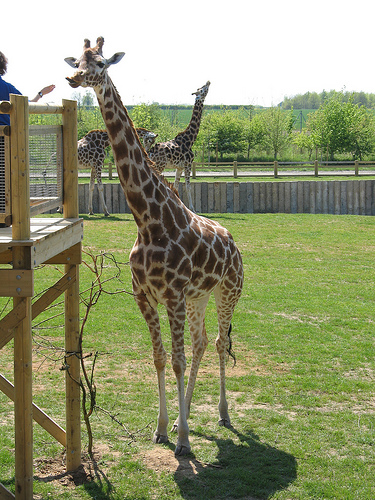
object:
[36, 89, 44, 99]
wrist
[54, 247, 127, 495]
vine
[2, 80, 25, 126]
shirt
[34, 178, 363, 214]
wall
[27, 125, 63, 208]
mesh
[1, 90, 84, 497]
bridge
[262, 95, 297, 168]
trees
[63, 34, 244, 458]
giraffe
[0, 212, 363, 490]
ground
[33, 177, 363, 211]
fence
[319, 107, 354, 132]
leaves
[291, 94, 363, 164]
tree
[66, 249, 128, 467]
branch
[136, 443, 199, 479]
spot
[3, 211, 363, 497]
grass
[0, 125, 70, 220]
wall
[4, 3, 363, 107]
sky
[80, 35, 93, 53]
horns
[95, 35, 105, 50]
ear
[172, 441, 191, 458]
hoof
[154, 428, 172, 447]
hoof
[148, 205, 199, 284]
spots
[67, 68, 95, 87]
nose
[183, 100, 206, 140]
neck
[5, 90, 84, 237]
railing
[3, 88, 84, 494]
platform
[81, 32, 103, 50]
ossicones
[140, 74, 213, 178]
giraffe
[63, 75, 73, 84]
tongue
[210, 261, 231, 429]
legs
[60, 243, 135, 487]
tree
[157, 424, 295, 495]
shadow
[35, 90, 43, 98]
watch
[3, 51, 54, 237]
woman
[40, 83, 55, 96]
right hand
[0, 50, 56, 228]
woman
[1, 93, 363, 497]
zoo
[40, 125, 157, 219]
giraffe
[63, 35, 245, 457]
animal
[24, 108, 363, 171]
field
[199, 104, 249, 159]
tree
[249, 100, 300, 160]
tree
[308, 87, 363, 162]
tree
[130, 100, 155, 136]
tree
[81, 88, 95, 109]
tree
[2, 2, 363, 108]
air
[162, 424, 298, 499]
shadow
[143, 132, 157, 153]
head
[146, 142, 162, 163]
butt